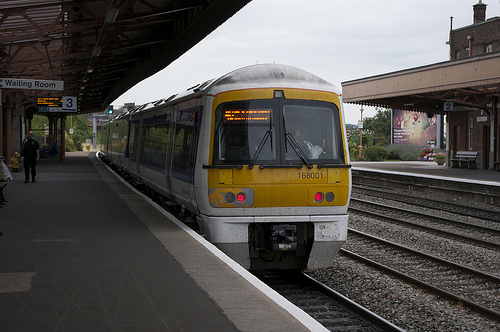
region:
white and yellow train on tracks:
[88, 62, 350, 275]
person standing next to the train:
[17, 126, 42, 181]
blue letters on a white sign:
[1, 72, 64, 91]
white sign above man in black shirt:
[2, 90, 66, 183]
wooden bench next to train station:
[446, 146, 480, 165]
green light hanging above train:
[103, 102, 116, 115]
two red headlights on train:
[217, 186, 340, 206]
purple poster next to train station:
[389, 98, 444, 158]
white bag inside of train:
[301, 140, 323, 160]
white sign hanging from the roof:
[62, 96, 78, 110]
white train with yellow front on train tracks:
[95, 58, 357, 291]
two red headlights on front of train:
[218, 183, 340, 209]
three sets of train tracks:
[298, 206, 495, 330]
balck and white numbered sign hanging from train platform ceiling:
[53, 89, 84, 118]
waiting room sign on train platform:
[2, 67, 70, 98]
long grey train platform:
[8, 138, 335, 330]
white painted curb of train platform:
[104, 157, 336, 328]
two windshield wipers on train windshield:
[244, 125, 318, 173]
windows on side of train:
[94, 107, 203, 187]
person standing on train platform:
[16, 124, 44, 189]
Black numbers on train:
[296, 169, 323, 181]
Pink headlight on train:
[314, 190, 323, 201]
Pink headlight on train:
[235, 191, 245, 201]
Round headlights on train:
[223, 190, 246, 203]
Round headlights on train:
[313, 190, 336, 202]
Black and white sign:
[61, 93, 78, 110]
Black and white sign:
[443, 99, 453, 111]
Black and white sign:
[0, 76, 65, 91]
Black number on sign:
[65, 96, 74, 106]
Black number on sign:
[444, 100, 450, 110]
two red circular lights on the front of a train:
[309, 191, 339, 203]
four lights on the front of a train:
[221, 189, 334, 204]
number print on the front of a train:
[292, 170, 326, 181]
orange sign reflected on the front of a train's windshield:
[223, 109, 271, 124]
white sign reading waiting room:
[4, 76, 65, 90]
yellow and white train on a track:
[98, 59, 353, 273]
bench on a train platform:
[449, 147, 481, 167]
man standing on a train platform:
[20, 127, 43, 184]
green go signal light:
[106, 104, 113, 116]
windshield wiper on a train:
[281, 127, 313, 169]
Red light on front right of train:
[233, 187, 248, 206]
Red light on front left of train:
[309, 190, 327, 205]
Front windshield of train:
[204, 92, 354, 170]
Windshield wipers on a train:
[246, 122, 318, 174]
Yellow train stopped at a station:
[126, 52, 361, 291]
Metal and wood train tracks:
[369, 222, 460, 306]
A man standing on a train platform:
[14, 122, 47, 184]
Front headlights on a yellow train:
[218, 184, 343, 211]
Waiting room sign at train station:
[1, 70, 67, 96]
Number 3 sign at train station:
[58, 92, 83, 115]